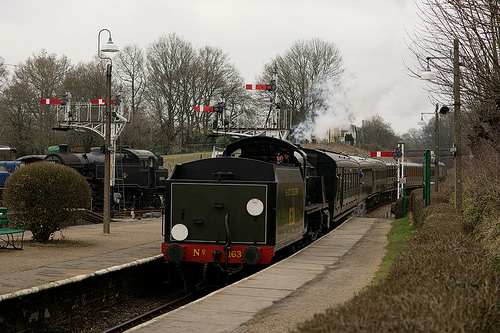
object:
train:
[158, 100, 470, 282]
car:
[158, 151, 312, 270]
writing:
[185, 241, 246, 259]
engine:
[161, 151, 309, 269]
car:
[318, 146, 371, 215]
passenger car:
[402, 160, 426, 191]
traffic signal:
[42, 93, 127, 136]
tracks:
[61, 260, 223, 330]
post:
[423, 150, 433, 208]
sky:
[1, 2, 413, 53]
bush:
[0, 157, 92, 244]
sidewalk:
[0, 206, 170, 297]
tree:
[141, 32, 194, 154]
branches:
[143, 30, 198, 111]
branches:
[402, 0, 497, 92]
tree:
[407, 0, 498, 139]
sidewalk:
[129, 208, 379, 331]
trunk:
[163, 94, 176, 154]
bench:
[0, 226, 25, 248]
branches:
[284, 35, 349, 88]